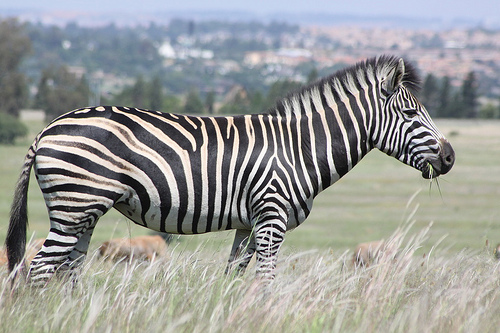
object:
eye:
[404, 109, 417, 115]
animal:
[15, 58, 454, 293]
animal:
[354, 241, 394, 267]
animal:
[100, 233, 169, 262]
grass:
[0, 118, 500, 333]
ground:
[0, 119, 500, 333]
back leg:
[57, 220, 98, 288]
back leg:
[25, 197, 115, 293]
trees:
[0, 17, 500, 142]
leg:
[250, 195, 289, 286]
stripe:
[20, 82, 441, 289]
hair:
[273, 54, 423, 115]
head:
[370, 59, 455, 179]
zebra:
[14, 58, 454, 290]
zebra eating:
[1, 52, 457, 312]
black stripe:
[325, 108, 349, 178]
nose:
[442, 142, 455, 165]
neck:
[299, 90, 372, 196]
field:
[5, 122, 469, 320]